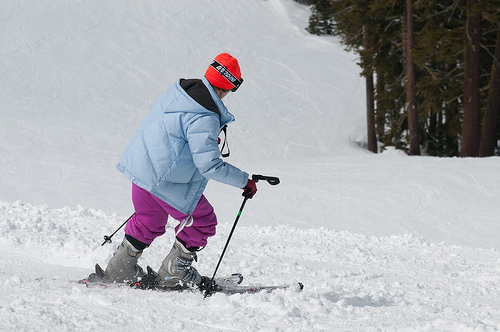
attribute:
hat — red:
[204, 50, 244, 90]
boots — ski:
[104, 237, 209, 291]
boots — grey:
[100, 230, 205, 286]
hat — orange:
[203, 54, 244, 92]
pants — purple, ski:
[122, 179, 218, 253]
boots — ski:
[100, 234, 207, 288]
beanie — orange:
[203, 50, 242, 91]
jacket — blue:
[141, 105, 252, 183]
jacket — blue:
[119, 76, 247, 221]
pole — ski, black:
[211, 171, 294, 275]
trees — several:
[298, 4, 494, 151]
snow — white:
[3, 5, 498, 331]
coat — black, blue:
[113, 80, 249, 215]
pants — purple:
[119, 182, 216, 260]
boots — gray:
[101, 235, 203, 295]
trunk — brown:
[357, 66, 390, 148]